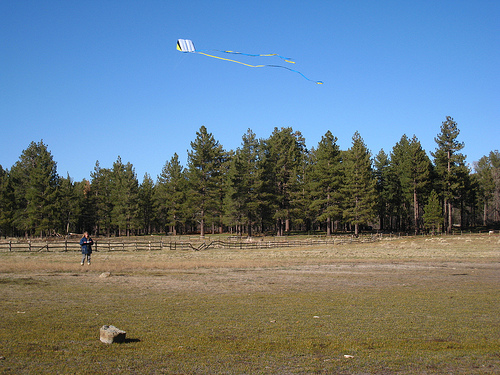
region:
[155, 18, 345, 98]
striped kite in sky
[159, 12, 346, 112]
kite flying across blue sky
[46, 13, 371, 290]
person flying kite in field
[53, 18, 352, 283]
girl flying kite in field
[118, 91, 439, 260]
tall trees behind wooden fence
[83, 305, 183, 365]
tree stump in middle of field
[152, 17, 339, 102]
blue and yellow striped kite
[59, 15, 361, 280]
girl wearing blue coat flying a kite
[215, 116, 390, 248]
dark green leaves on trees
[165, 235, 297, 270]
broken part of wooden fence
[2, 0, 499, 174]
a clear blue sky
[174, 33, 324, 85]
a kite in flight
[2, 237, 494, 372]
a green grassy field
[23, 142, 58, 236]
an evergreen tree in distance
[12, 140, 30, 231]
an evergreen tree in distance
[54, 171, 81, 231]
an evergreen tree in distance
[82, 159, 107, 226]
an evergreen tree in distance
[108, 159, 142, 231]
an evergreen tree in distance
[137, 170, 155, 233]
an evergreen tree in distance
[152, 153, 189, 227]
an evergreen tree in distance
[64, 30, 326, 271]
person flying a kite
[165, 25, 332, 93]
a kite in the sky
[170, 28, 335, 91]
kite has long tail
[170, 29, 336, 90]
kite has two tails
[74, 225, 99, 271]
woman has long hair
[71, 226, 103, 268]
woman has blue coat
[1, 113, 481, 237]
trees on side a field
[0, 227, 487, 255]
a fence behind a woman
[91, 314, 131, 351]
a piece of stone on a field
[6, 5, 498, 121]
a kite in a blue sky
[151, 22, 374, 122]
the kite is flying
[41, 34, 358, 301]
a woman flying a kite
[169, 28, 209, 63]
a colorful kite in a sky.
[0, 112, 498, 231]
a forest of green trees.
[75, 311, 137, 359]
a tree stump in a field.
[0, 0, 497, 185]
a clear blue sky.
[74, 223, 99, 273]
a man standing in a field.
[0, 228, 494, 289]
a field of dry grass.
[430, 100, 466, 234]
a very tall pine tree.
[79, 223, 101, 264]
a person standing under a blue sky.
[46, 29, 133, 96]
a section of a blue sky.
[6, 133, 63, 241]
a tall green tree.